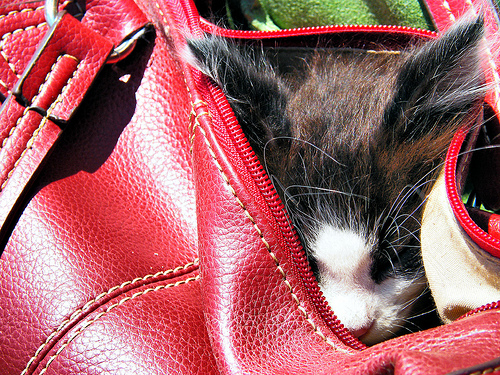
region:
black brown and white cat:
[177, 13, 497, 346]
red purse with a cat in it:
[0, 0, 499, 374]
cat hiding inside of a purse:
[186, 9, 498, 340]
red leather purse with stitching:
[0, 0, 497, 374]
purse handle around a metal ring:
[2, 0, 151, 240]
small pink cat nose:
[331, 298, 378, 345]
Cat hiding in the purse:
[145, 11, 495, 351]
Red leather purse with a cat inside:
[11, 10, 498, 374]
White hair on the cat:
[223, 111, 489, 338]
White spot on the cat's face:
[289, 198, 431, 350]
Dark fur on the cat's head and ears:
[191, 4, 496, 216]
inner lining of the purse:
[409, 178, 496, 335]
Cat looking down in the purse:
[259, 135, 488, 354]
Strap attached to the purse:
[0, 3, 175, 254]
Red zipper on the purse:
[176, 5, 491, 370]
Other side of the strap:
[388, 4, 498, 266]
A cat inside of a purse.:
[174, 0, 445, 342]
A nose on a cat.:
[311, 258, 383, 336]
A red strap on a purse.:
[1, 0, 170, 256]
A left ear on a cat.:
[389, 6, 498, 113]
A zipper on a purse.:
[183, 0, 443, 51]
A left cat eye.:
[364, 239, 421, 293]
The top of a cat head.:
[291, 45, 418, 153]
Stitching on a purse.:
[21, 257, 201, 374]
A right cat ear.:
[174, 29, 289, 123]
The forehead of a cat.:
[298, 211, 375, 337]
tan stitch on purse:
[312, 327, 327, 339]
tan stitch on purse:
[295, 304, 308, 316]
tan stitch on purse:
[291, 292, 301, 304]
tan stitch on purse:
[283, 278, 292, 290]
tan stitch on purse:
[276, 262, 287, 277]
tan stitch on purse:
[268, 248, 278, 261]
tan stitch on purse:
[165, 282, 176, 287]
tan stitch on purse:
[130, 290, 142, 297]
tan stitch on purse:
[104, 302, 117, 311]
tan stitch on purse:
[67, 332, 82, 342]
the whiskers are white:
[387, 186, 443, 296]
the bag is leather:
[67, 122, 188, 270]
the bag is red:
[60, 120, 263, 327]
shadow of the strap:
[82, 77, 142, 168]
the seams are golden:
[75, 270, 200, 341]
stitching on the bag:
[79, 242, 213, 332]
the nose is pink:
[347, 324, 367, 354]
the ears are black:
[235, 54, 476, 140]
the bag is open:
[184, 30, 499, 357]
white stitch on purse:
[23, 355, 35, 372]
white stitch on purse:
[32, 343, 47, 358]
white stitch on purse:
[43, 330, 58, 342]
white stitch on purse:
[56, 320, 68, 330]